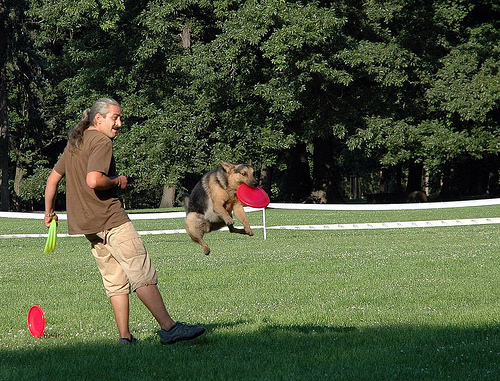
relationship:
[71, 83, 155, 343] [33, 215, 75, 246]
man holds frisbee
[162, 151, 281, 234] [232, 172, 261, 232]
dog has frisbee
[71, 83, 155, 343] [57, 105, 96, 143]
man has ponytail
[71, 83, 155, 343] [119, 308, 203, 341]
man wears shoes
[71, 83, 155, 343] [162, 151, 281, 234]
man plays with dog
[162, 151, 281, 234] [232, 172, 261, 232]
dog catches frisbee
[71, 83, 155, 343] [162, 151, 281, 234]
man with dog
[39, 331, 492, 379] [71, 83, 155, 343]
shadow behind man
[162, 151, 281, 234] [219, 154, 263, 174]
dog has ears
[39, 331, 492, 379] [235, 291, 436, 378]
shadow on grass